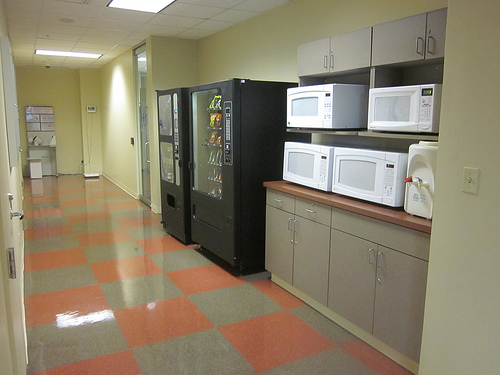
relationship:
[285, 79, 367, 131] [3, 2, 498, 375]
microwave sitting in a break room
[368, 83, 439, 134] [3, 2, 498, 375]
microwave sitting in a break room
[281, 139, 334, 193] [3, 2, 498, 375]
microwave sitting in a break room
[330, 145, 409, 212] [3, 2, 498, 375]
microwave sitting in a break room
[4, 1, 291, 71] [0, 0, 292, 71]
tiles are on tiles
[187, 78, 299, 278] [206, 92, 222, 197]
vending machine holding snacks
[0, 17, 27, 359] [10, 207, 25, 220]
door has a handle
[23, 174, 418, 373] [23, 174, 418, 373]
floor has a floor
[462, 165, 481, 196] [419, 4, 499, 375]
light switch affixed to wall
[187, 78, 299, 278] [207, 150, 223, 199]
vending machine holds candy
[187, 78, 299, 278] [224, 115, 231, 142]
vending machine has buttons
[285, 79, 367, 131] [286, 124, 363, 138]
microwave sitting on a shelf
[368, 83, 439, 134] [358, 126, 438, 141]
microwave sitting on a shelf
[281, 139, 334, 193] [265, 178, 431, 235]
microwave sitting on a shelf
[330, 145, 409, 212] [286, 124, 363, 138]
microwave sitting on a shelf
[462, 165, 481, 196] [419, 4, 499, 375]
light switch on wall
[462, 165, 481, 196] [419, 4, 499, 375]
light switch on a wall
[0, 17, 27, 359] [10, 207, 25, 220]
door has metal handle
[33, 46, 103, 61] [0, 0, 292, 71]
light in tiles